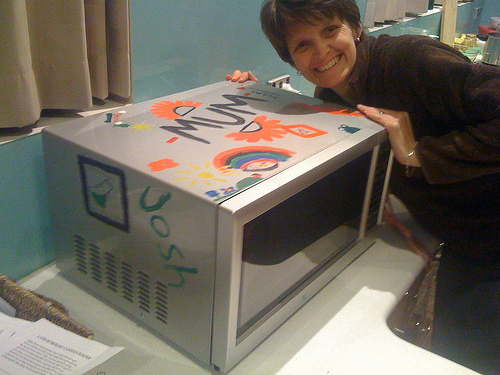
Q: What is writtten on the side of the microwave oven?
A: Josh.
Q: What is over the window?
A: Curtain.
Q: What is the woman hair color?
A: Brown.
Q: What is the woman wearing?
A: Sweater.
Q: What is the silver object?
A: Microwave.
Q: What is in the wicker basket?
A: Papers.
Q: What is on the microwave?
A: Drawings.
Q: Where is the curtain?
A: On the window.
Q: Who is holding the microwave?
A: The woman.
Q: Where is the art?
A: On top of microwave.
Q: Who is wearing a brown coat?
A: The woman.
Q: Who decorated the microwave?
A: Children.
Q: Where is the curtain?
A: Behind the microwave.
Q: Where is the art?
A: On the microwave.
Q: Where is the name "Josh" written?
A: On microwave.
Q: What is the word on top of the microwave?
A: Mum.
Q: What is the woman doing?
A: Smiling.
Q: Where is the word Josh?
A: On the side of the microwave.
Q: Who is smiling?
A: The woman with the microwave.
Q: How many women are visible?
A: One.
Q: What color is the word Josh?
A: Green.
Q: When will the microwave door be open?
A: When it is about to be used.